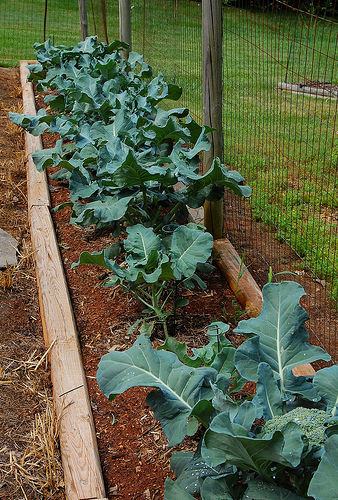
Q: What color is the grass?
A: Green.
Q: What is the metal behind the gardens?
A: A fence.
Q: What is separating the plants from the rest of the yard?
A: A piece of wood.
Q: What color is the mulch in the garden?
A: Red.